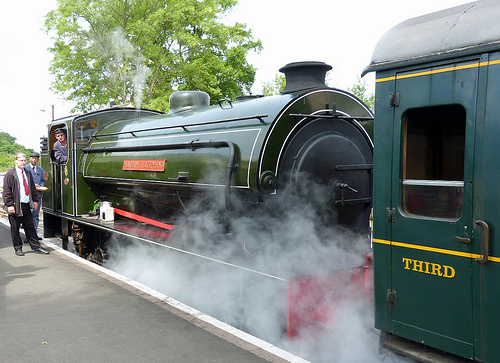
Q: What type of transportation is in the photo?
A: Train.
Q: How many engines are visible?
A: 1.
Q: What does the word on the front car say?
A: Third.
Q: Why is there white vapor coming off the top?
A: Steam.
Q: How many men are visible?
A: 3.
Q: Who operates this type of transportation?
A: Engineer.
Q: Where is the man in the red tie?
A: Far left.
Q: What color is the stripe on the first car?
A: Yellow.